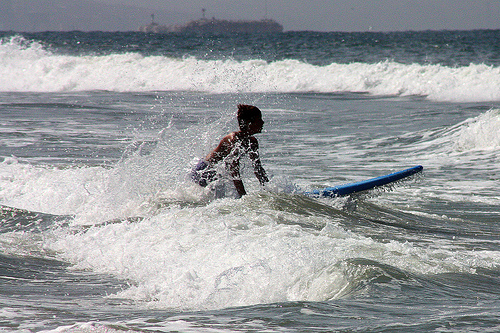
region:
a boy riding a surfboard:
[66, 105, 420, 211]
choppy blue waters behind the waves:
[89, 30, 439, 55]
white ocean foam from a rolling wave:
[0, 47, 433, 99]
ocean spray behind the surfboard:
[61, 120, 203, 233]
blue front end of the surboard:
[286, 160, 432, 212]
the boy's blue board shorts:
[177, 158, 224, 203]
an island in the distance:
[112, 7, 293, 42]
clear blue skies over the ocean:
[279, 7, 430, 27]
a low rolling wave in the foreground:
[114, 214, 421, 302]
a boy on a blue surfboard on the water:
[117, 75, 434, 226]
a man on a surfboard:
[103, 16, 499, 311]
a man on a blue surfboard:
[96, 33, 458, 282]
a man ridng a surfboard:
[121, 62, 443, 298]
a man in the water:
[118, 61, 485, 303]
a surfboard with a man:
[79, 41, 444, 286]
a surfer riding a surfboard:
[40, 39, 497, 307]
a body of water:
[8, 61, 103, 158]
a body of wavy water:
[15, 18, 300, 149]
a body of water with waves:
[10, 21, 249, 205]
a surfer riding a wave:
[23, 16, 483, 321]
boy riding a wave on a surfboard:
[162, 88, 431, 215]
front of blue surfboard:
[288, 159, 429, 199]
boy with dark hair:
[230, 95, 269, 138]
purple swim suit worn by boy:
[184, 151, 225, 195]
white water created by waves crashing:
[90, 114, 190, 302]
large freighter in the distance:
[140, 12, 286, 37]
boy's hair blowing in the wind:
[227, 98, 270, 136]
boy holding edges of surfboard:
[172, 99, 426, 206]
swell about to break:
[11, 24, 418, 98]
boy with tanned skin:
[203, 101, 278, 197]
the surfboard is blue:
[275, 164, 450, 232]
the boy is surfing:
[158, 64, 322, 324]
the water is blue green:
[94, 29, 249, 76]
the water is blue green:
[223, 24, 350, 61]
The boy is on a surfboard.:
[170, 97, 428, 213]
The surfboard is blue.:
[175, 95, 430, 216]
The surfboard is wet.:
[190, 95, 430, 205]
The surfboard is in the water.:
[185, 95, 435, 215]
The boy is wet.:
[155, 90, 430, 216]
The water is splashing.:
[110, 95, 440, 235]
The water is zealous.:
[0, 20, 495, 330]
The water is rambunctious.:
[0, 10, 495, 330]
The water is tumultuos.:
[0, 10, 495, 325]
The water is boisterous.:
[0, 13, 499, 328]